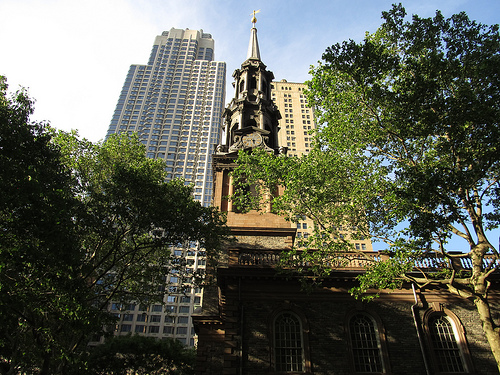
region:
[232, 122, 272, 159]
clock on tall tower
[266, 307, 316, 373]
window with circular top on it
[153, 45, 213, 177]
white tall building on the left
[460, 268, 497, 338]
brown tree trunk on right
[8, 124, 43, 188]
tree with green leaves on left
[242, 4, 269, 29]
pointed spire on top of clock tower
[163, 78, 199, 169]
long line of windows in a row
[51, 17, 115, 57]
white area of clouds in sky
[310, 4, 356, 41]
blue area of sky in the upper right of photo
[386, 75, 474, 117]
tree with green leaves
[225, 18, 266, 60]
church has pointed top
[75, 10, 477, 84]
sky is blue and white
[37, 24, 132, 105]
puffy clouds in sky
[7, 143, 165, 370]
green trees next to church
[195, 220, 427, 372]
church has brown exterior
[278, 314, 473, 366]
church has arched windows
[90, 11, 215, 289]
tall and grey skyscraper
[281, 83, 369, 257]
tall and brown skyscraper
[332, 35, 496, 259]
green trees on right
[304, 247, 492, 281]
brown rail on church roof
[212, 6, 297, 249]
peak of a building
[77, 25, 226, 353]
a windowed high rise building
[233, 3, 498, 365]
a tree with bright green leaves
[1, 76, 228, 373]
a tree with bright green leaves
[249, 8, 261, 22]
a cross atop a building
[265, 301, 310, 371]
exterior window on a building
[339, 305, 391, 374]
exterior window on a building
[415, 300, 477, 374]
exterior window on a building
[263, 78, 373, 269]
a light brown building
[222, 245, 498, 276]
a stone railing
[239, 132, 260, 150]
white clock in tower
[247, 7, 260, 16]
weather vane on tower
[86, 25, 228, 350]
brick and glass skyscraper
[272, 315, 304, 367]
wood window in stone building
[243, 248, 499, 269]
stone fence on building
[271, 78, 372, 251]
tan stone skyscraper building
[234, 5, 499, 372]
tree with green leaves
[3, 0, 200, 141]
white cloud in sky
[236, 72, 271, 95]
grey stone bell tower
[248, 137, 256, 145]
black hands on clock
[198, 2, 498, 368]
the tower of an old building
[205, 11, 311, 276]
a tower on a building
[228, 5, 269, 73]
the steeple of tower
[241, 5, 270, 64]
a weather vane on top of steeple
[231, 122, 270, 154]
a clock in front a tower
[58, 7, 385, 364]
two modern buildings on back of old building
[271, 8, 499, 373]
a tree on front a building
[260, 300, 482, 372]
arch windows on side a building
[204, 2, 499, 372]
tree has green leaves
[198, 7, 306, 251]
tower is gray and brown